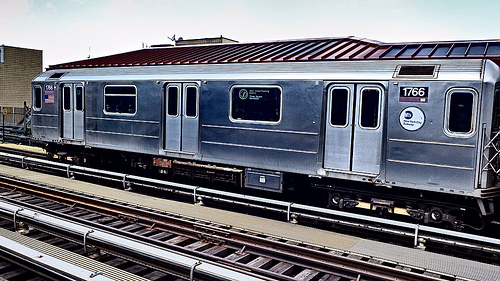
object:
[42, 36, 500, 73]
roof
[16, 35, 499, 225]
train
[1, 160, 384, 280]
track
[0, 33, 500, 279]
station